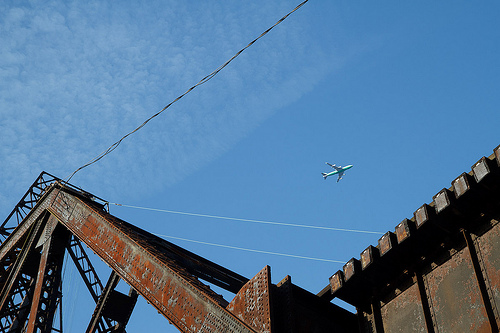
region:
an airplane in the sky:
[318, 159, 353, 180]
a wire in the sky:
[53, 15, 350, 157]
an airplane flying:
[320, 162, 355, 180]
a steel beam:
[51, 192, 273, 332]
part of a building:
[293, 160, 465, 305]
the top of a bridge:
[2, 183, 127, 325]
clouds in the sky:
[32, 38, 129, 102]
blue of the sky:
[368, 90, 461, 145]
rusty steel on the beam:
[56, 201, 271, 326]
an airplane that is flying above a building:
[316, 157, 352, 179]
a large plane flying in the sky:
[318, 155, 361, 195]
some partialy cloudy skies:
[65, 23, 174, 88]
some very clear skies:
[377, 23, 486, 169]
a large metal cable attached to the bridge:
[68, 0, 291, 185]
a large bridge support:
[1, 163, 143, 332]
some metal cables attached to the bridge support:
[101, 201, 411, 248]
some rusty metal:
[191, 274, 283, 331]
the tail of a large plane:
[317, 170, 329, 184]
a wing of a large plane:
[323, 156, 343, 172]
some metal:
[369, 215, 499, 325]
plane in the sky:
[311, 156, 361, 190]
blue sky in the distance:
[340, 57, 446, 138]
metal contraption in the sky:
[8, 183, 363, 325]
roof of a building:
[316, 169, 496, 289]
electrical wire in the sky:
[76, 82, 227, 131]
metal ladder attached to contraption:
[66, 245, 103, 291]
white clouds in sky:
[13, 60, 133, 100]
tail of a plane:
[319, 170, 330, 185]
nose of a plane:
[343, 158, 358, 170]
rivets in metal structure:
[246, 280, 266, 305]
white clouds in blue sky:
[5, 9, 71, 48]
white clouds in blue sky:
[282, 35, 305, 79]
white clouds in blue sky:
[308, 44, 358, 83]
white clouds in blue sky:
[180, 87, 205, 129]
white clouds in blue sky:
[223, 134, 258, 180]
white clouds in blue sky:
[374, 5, 470, 149]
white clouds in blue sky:
[60, 48, 129, 117]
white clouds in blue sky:
[146, 44, 217, 106]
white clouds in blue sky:
[130, 139, 199, 194]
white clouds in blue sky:
[223, 32, 292, 103]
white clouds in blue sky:
[46, 2, 121, 62]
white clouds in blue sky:
[305, 121, 344, 151]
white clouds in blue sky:
[367, 52, 417, 110]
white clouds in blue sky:
[208, 73, 309, 146]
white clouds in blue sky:
[110, 78, 210, 163]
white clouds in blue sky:
[32, 32, 92, 74]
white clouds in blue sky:
[191, 96, 214, 137]